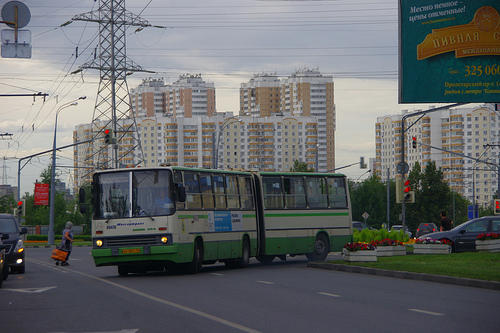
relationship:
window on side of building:
[280, 124, 291, 142] [74, 60, 334, 176]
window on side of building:
[296, 129, 303, 136] [302, 88, 333, 172]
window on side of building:
[191, 102, 198, 109] [165, 70, 211, 116]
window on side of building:
[461, 128, 470, 137] [449, 104, 497, 208]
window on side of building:
[473, 178, 482, 185] [449, 104, 497, 208]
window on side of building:
[473, 123, 482, 130] [449, 104, 497, 208]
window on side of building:
[479, 114, 488, 123] [441, 98, 497, 210]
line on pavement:
[411, 308, 444, 318] [0, 249, 496, 330]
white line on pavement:
[72, 266, 149, 310] [0, 249, 496, 330]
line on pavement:
[23, 255, 259, 330] [0, 249, 496, 330]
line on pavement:
[32, 258, 265, 329] [2, 243, 497, 327]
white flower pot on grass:
[411, 235, 454, 257] [334, 251, 497, 285]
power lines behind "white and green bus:
[149, 7, 403, 71] [79, 166, 355, 275]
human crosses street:
[54, 221, 73, 268] [5, 248, 495, 331]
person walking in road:
[57, 220, 71, 263] [2, 282, 396, 327]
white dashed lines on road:
[214, 268, 353, 312] [6, 282, 493, 323]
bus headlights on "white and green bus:
[96, 240, 103, 247] [79, 166, 355, 275]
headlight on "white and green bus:
[162, 233, 169, 242] [79, 166, 355, 275]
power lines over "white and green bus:
[61, 68, 64, 71] [79, 166, 355, 275]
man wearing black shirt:
[437, 211, 449, 227] [441, 217, 452, 230]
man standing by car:
[437, 211, 449, 227] [415, 217, 498, 251]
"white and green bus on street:
[79, 166, 355, 275] [12, 286, 462, 331]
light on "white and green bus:
[161, 235, 168, 242] [79, 166, 355, 275]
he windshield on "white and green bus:
[92, 169, 175, 218] [79, 166, 355, 275]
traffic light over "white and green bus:
[101, 128, 110, 144] [79, 166, 355, 275]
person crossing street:
[61, 221, 74, 266] [4, 282, 467, 325]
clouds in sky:
[170, 8, 359, 55] [13, 2, 389, 71]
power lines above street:
[73, 17, 78, 26] [12, 286, 462, 331]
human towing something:
[61, 217, 76, 263] [51, 245, 72, 265]